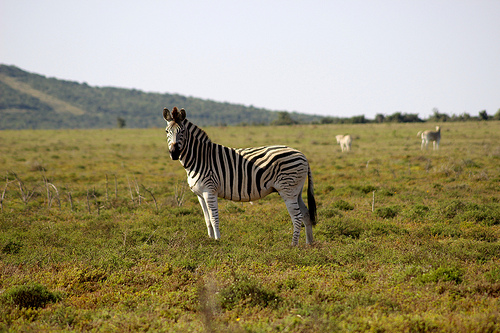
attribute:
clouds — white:
[419, 25, 475, 92]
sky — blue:
[8, 10, 485, 109]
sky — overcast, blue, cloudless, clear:
[2, 1, 482, 117]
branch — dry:
[137, 184, 157, 208]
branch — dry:
[43, 180, 62, 197]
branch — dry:
[9, 171, 29, 201]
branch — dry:
[177, 181, 187, 207]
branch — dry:
[1, 177, 9, 201]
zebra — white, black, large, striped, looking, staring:
[160, 106, 321, 249]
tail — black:
[305, 162, 319, 229]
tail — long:
[305, 160, 318, 227]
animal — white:
[334, 130, 354, 150]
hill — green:
[1, 63, 348, 128]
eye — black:
[179, 128, 186, 135]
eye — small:
[179, 128, 187, 134]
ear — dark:
[161, 106, 171, 125]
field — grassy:
[1, 119, 484, 330]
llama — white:
[334, 132, 354, 152]